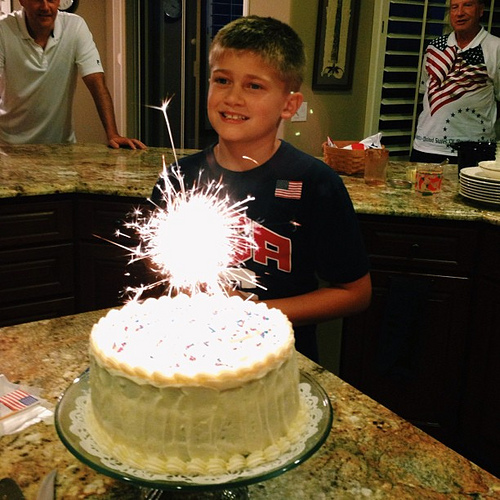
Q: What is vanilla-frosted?
A: Cake.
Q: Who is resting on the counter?
A: A man.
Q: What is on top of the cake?
A: A sparkler.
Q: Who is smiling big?
A: The child.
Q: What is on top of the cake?
A: Sparkler.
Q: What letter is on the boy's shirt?
A: A.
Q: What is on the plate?
A: Cake.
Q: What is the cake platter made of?
A: Glass.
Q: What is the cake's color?
A: White.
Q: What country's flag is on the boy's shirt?
A: United States.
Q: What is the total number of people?
A: 3.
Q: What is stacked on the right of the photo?
A: Plates.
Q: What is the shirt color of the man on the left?
A: White.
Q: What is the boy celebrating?
A: Birthday.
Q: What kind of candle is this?
A: Sparkler.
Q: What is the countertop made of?
A: Granite.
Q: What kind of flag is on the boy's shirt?
A: American flag.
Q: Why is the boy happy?
A: It's special occasion.